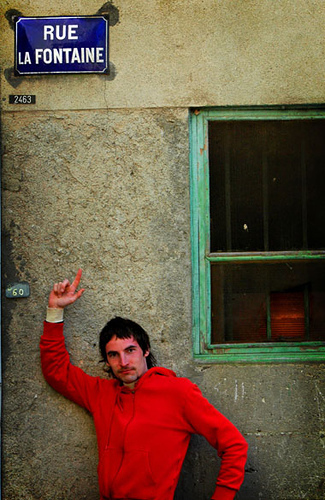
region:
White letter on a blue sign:
[40, 21, 56, 42]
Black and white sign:
[4, 91, 42, 106]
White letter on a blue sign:
[53, 22, 64, 41]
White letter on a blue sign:
[65, 21, 79, 44]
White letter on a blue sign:
[17, 50, 26, 66]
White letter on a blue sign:
[23, 47, 33, 67]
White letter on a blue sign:
[34, 48, 43, 65]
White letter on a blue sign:
[42, 49, 55, 71]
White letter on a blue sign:
[53, 48, 62, 65]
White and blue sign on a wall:
[9, 8, 116, 88]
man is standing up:
[43, 265, 225, 493]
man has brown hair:
[85, 311, 155, 363]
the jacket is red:
[25, 326, 229, 495]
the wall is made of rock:
[233, 380, 301, 473]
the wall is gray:
[247, 382, 322, 479]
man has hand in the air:
[36, 269, 93, 351]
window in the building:
[181, 91, 319, 363]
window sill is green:
[199, 321, 322, 365]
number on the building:
[0, 273, 37, 322]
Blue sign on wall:
[17, 14, 106, 73]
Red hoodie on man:
[42, 321, 249, 498]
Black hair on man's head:
[93, 316, 153, 353]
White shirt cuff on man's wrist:
[47, 306, 63, 323]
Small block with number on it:
[4, 280, 32, 299]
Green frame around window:
[188, 108, 324, 359]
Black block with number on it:
[8, 92, 35, 105]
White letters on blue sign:
[19, 22, 104, 68]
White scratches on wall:
[228, 378, 245, 404]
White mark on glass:
[239, 220, 250, 232]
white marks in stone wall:
[221, 374, 251, 395]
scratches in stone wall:
[272, 439, 322, 498]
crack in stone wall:
[253, 426, 324, 438]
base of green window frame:
[198, 342, 323, 360]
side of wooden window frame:
[190, 109, 208, 356]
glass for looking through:
[212, 124, 319, 249]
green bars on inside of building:
[257, 126, 276, 340]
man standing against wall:
[43, 268, 248, 499]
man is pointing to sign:
[30, 257, 264, 497]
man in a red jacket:
[34, 263, 262, 497]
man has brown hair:
[41, 267, 260, 495]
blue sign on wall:
[8, 7, 117, 84]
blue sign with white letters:
[12, 8, 115, 83]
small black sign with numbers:
[8, 92, 39, 110]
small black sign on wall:
[6, 86, 39, 114]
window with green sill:
[181, 101, 323, 374]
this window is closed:
[180, 89, 316, 377]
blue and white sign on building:
[9, 9, 123, 84]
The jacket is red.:
[79, 379, 200, 466]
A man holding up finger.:
[39, 268, 87, 309]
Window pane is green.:
[181, 218, 323, 374]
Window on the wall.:
[172, 142, 322, 353]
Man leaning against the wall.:
[41, 290, 229, 492]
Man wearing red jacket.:
[72, 317, 206, 489]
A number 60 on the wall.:
[5, 277, 42, 305]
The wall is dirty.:
[28, 178, 184, 329]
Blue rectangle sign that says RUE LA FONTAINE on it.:
[13, 15, 110, 75]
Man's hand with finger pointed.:
[48, 268, 85, 305]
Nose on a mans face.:
[117, 352, 128, 367]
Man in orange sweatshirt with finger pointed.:
[40, 268, 247, 498]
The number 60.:
[12, 287, 23, 295]